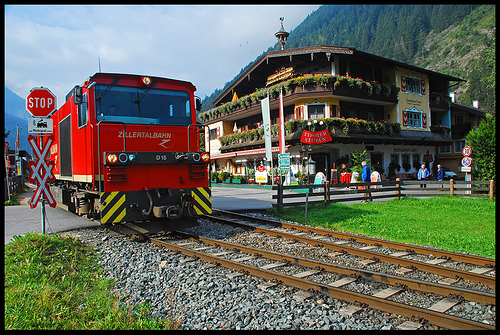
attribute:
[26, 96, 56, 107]
letters — white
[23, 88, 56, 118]
stop sign — red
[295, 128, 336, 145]
banner — red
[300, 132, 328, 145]
letters — gold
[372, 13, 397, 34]
leaf — green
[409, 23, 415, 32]
leaf — green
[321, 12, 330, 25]
leaf — green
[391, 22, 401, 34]
leaf — green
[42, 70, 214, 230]
car — train, bright red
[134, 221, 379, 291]
stones — grey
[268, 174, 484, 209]
fence — wooden, low, brown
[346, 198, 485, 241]
area — grassy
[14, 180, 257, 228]
crossing — railroad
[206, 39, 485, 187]
building — large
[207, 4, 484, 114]
hill — wooded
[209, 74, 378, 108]
plants — flowering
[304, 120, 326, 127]
lights — three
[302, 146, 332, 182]
entrance — buildings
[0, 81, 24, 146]
sections — small , blue mountains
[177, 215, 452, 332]
tracks — brown, rail road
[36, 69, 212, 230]
train — red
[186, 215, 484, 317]
tracks — train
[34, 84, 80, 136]
mirror — sideview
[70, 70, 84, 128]
mirror — side